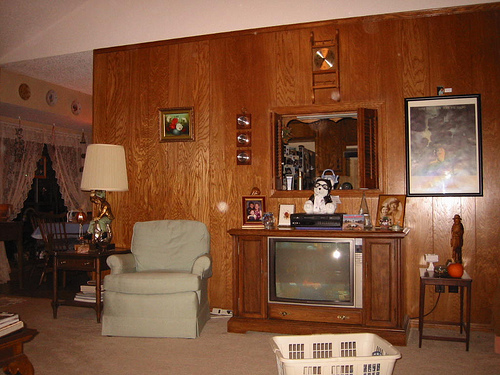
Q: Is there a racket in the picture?
A: No, there are no rackets.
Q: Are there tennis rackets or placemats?
A: No, there are no tennis rackets or placemats.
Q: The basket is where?
A: The basket is on the floor.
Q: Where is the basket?
A: The basket is on the floor.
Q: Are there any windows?
A: Yes, there is a window.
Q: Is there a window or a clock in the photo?
A: Yes, there is a window.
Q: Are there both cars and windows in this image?
A: No, there is a window but no cars.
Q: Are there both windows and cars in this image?
A: No, there is a window but no cars.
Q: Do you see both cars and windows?
A: No, there is a window but no cars.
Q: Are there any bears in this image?
A: Yes, there is a bear.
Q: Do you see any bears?
A: Yes, there is a bear.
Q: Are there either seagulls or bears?
A: Yes, there is a bear.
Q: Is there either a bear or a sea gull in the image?
A: Yes, there is a bear.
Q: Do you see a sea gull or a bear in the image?
A: Yes, there is a bear.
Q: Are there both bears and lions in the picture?
A: No, there is a bear but no lions.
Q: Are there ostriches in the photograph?
A: No, there are no ostriches.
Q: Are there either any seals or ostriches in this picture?
A: No, there are no ostriches or seals.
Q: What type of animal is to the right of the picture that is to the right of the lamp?
A: The animal is a bear.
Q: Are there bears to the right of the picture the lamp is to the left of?
A: Yes, there is a bear to the right of the picture.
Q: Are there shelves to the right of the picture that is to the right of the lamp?
A: No, there is a bear to the right of the picture.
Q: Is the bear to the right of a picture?
A: Yes, the bear is to the right of a picture.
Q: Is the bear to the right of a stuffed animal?
A: No, the bear is to the right of a picture.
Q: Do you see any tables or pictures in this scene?
A: Yes, there is a table.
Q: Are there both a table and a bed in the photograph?
A: No, there is a table but no beds.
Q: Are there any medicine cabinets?
A: No, there are no medicine cabinets.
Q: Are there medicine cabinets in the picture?
A: No, there are no medicine cabinets.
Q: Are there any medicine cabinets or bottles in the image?
A: No, there are no medicine cabinets or bottles.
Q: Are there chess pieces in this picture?
A: No, there are no chess pieces.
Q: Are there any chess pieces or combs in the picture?
A: No, there are no chess pieces or combs.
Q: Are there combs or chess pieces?
A: No, there are no chess pieces or combs.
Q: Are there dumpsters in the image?
A: No, there are no dumpsters.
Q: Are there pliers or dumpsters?
A: No, there are no dumpsters or pliers.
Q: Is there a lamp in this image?
A: Yes, there is a lamp.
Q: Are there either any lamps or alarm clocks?
A: Yes, there is a lamp.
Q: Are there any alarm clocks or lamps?
A: Yes, there is a lamp.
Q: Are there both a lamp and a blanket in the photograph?
A: No, there is a lamp but no blankets.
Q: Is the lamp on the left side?
A: Yes, the lamp is on the left of the image.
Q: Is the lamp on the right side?
A: No, the lamp is on the left of the image.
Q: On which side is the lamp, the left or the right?
A: The lamp is on the left of the image.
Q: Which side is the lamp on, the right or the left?
A: The lamp is on the left of the image.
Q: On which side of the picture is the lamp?
A: The lamp is on the left of the image.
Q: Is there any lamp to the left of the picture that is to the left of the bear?
A: Yes, there is a lamp to the left of the picture.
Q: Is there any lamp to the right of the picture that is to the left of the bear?
A: No, the lamp is to the left of the picture.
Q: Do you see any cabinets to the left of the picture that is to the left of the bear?
A: No, there is a lamp to the left of the picture.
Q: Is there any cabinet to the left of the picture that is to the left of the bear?
A: No, there is a lamp to the left of the picture.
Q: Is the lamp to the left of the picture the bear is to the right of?
A: Yes, the lamp is to the left of the picture.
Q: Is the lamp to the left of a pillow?
A: No, the lamp is to the left of the picture.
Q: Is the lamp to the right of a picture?
A: No, the lamp is to the left of a picture.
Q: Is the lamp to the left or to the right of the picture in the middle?
A: The lamp is to the left of the picture.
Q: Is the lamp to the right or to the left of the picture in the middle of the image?
A: The lamp is to the left of the picture.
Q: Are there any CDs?
A: No, there are no cds.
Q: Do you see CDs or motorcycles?
A: No, there are no CDs or motorcycles.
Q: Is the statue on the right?
A: Yes, the statue is on the right of the image.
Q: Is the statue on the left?
A: No, the statue is on the right of the image.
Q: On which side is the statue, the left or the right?
A: The statue is on the right of the image.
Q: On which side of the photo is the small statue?
A: The statue is on the right of the image.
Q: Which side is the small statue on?
A: The statue is on the right of the image.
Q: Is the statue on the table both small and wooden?
A: Yes, the statue is small and wooden.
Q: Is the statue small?
A: Yes, the statue is small.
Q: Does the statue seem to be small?
A: Yes, the statue is small.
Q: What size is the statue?
A: The statue is small.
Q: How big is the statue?
A: The statue is small.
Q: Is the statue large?
A: No, the statue is small.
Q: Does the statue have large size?
A: No, the statue is small.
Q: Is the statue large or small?
A: The statue is small.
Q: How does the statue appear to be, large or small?
A: The statue is small.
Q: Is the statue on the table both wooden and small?
A: Yes, the statue is wooden and small.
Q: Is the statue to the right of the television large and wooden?
A: No, the statue is wooden but small.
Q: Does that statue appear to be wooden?
A: Yes, the statue is wooden.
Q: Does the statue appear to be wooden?
A: Yes, the statue is wooden.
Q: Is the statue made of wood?
A: Yes, the statue is made of wood.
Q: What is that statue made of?
A: The statue is made of wood.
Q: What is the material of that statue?
A: The statue is made of wood.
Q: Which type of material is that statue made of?
A: The statue is made of wood.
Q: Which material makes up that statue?
A: The statue is made of wood.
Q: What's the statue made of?
A: The statue is made of wood.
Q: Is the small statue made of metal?
A: No, the statue is made of wood.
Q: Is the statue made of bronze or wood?
A: The statue is made of wood.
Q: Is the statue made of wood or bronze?
A: The statue is made of wood.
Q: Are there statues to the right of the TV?
A: Yes, there is a statue to the right of the TV.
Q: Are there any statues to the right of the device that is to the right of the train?
A: Yes, there is a statue to the right of the TV.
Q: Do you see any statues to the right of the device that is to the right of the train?
A: Yes, there is a statue to the right of the TV.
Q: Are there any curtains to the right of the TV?
A: No, there is a statue to the right of the TV.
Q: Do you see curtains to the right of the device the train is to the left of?
A: No, there is a statue to the right of the TV.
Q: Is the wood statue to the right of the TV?
A: Yes, the statue is to the right of the TV.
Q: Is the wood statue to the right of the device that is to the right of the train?
A: Yes, the statue is to the right of the TV.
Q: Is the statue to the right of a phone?
A: No, the statue is to the right of the TV.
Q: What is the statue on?
A: The statue is on the table.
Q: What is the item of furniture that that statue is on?
A: The piece of furniture is a table.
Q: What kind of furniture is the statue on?
A: The statue is on the table.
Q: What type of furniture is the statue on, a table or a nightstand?
A: The statue is on a table.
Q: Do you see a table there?
A: Yes, there is a table.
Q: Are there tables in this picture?
A: Yes, there is a table.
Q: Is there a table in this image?
A: Yes, there is a table.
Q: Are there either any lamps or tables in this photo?
A: Yes, there is a table.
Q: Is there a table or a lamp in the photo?
A: Yes, there is a table.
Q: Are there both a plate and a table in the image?
A: Yes, there are both a table and a plate.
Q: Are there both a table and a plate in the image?
A: Yes, there are both a table and a plate.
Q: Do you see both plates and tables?
A: Yes, there are both a table and a plate.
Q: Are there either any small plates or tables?
A: Yes, there is a small table.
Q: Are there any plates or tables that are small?
A: Yes, the table is small.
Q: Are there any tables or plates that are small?
A: Yes, the table is small.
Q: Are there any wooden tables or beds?
A: Yes, there is a wood table.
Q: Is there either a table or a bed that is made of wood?
A: Yes, the table is made of wood.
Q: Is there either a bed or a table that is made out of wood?
A: Yes, the table is made of wood.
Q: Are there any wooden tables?
A: Yes, there is a wood table.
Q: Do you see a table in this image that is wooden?
A: Yes, there is a table that is wooden.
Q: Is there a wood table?
A: Yes, there is a table that is made of wood.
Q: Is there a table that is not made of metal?
A: Yes, there is a table that is made of wood.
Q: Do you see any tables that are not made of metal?
A: Yes, there is a table that is made of wood.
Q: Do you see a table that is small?
A: Yes, there is a small table.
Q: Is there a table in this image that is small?
A: Yes, there is a table that is small.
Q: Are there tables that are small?
A: Yes, there is a table that is small.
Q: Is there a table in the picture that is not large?
A: Yes, there is a small table.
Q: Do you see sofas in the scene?
A: No, there are no sofas.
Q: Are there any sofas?
A: No, there are no sofas.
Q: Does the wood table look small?
A: Yes, the table is small.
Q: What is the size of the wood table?
A: The table is small.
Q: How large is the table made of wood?
A: The table is small.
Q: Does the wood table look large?
A: No, the table is small.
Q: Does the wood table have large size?
A: No, the table is small.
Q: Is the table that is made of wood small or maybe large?
A: The table is small.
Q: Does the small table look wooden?
A: Yes, the table is wooden.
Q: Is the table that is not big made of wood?
A: Yes, the table is made of wood.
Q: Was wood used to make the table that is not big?
A: Yes, the table is made of wood.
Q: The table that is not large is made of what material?
A: The table is made of wood.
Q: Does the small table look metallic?
A: No, the table is wooden.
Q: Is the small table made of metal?
A: No, the table is made of wood.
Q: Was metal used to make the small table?
A: No, the table is made of wood.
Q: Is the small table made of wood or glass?
A: The table is made of wood.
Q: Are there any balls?
A: No, there are no balls.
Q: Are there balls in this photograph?
A: No, there are no balls.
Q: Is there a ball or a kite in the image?
A: No, there are no balls or kites.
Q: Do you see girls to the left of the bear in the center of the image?
A: No, there is a picture to the left of the bear.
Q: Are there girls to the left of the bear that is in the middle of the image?
A: No, there is a picture to the left of the bear.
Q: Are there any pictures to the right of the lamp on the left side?
A: Yes, there is a picture to the right of the lamp.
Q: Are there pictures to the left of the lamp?
A: No, the picture is to the right of the lamp.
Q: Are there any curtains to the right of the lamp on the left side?
A: No, there is a picture to the right of the lamp.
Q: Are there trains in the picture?
A: Yes, there is a train.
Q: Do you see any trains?
A: Yes, there is a train.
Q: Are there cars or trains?
A: Yes, there is a train.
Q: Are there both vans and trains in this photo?
A: No, there is a train but no vans.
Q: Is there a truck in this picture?
A: No, there are no trucks.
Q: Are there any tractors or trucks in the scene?
A: No, there are no trucks or tractors.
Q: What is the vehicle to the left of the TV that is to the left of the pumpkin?
A: The vehicle is a train.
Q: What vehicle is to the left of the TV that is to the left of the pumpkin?
A: The vehicle is a train.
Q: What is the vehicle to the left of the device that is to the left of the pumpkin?
A: The vehicle is a train.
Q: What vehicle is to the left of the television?
A: The vehicle is a train.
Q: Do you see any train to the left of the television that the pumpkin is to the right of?
A: Yes, there is a train to the left of the television.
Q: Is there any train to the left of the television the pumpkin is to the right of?
A: Yes, there is a train to the left of the television.